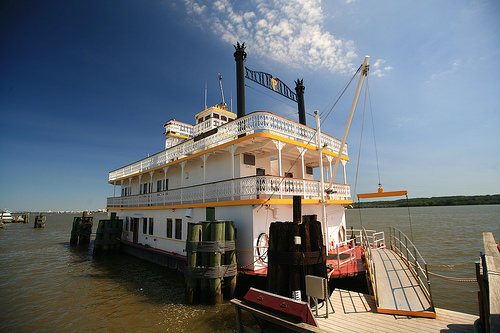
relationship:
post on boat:
[230, 38, 249, 138] [105, 41, 439, 319]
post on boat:
[292, 77, 307, 127] [105, 41, 439, 319]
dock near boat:
[226, 277, 499, 332] [105, 41, 439, 319]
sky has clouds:
[1, 1, 500, 212] [178, 0, 389, 79]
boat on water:
[105, 41, 439, 319] [0, 203, 499, 330]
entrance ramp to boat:
[360, 246, 434, 315] [105, 41, 439, 319]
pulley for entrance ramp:
[355, 51, 412, 202] [360, 246, 434, 315]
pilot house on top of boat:
[191, 104, 239, 135] [105, 41, 439, 319]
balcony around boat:
[107, 111, 350, 184] [105, 41, 439, 319]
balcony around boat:
[105, 175, 354, 210] [105, 41, 439, 319]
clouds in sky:
[178, 0, 389, 79] [1, 1, 500, 212]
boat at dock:
[105, 41, 439, 319] [226, 277, 499, 332]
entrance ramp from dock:
[360, 246, 434, 315] [226, 277, 499, 332]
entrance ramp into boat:
[360, 246, 434, 315] [105, 41, 439, 319]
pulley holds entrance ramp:
[355, 51, 412, 202] [360, 246, 434, 315]